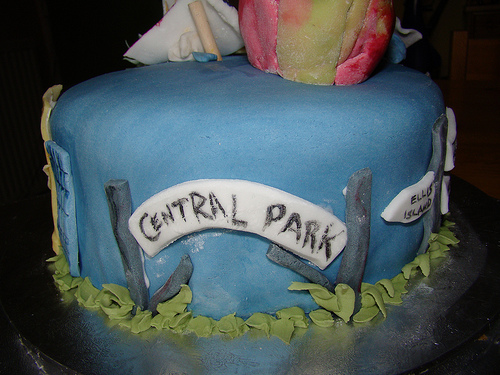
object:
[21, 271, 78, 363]
platter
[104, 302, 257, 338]
grass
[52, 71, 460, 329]
cake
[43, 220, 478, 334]
leaves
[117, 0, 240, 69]
cloth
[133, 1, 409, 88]
fondant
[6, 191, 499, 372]
metal tray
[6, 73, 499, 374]
table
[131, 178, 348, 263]
frosting sign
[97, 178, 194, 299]
stick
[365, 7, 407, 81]
toppings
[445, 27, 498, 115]
chair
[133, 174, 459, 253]
words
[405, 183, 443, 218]
letters